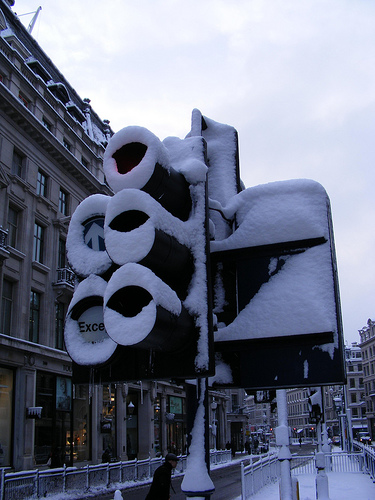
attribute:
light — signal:
[97, 100, 327, 386]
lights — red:
[266, 424, 314, 431]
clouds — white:
[44, 3, 259, 51]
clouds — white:
[113, 66, 256, 114]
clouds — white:
[326, 96, 365, 127]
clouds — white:
[343, 219, 360, 261]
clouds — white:
[273, 20, 321, 52]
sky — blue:
[10, 0, 373, 346]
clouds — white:
[12, 0, 374, 345]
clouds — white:
[102, 10, 222, 63]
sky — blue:
[50, 1, 373, 89]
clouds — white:
[303, 39, 344, 123]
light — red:
[310, 426, 315, 429]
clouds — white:
[248, 65, 332, 133]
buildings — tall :
[138, 197, 373, 471]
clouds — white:
[121, 95, 185, 137]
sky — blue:
[143, 38, 228, 67]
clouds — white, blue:
[110, 75, 189, 121]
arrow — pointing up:
[71, 208, 113, 264]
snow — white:
[85, 199, 105, 212]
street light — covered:
[64, 109, 346, 400]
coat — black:
[149, 461, 172, 499]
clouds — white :
[45, 4, 308, 68]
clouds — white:
[34, 6, 361, 190]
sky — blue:
[19, 7, 364, 314]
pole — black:
[176, 375, 223, 498]